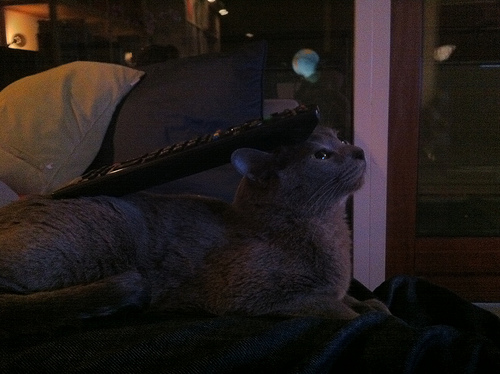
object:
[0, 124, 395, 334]
cat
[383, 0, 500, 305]
door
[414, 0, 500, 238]
window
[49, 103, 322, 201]
remote control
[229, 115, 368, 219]
head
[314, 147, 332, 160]
eye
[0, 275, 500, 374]
blanket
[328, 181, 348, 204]
wiskers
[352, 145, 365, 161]
nose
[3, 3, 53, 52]
light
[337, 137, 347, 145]
eye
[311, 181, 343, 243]
whiskers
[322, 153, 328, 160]
light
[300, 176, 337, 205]
whiskers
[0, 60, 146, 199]
pillow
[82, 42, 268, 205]
pillow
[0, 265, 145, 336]
tail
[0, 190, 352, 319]
body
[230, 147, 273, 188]
ear